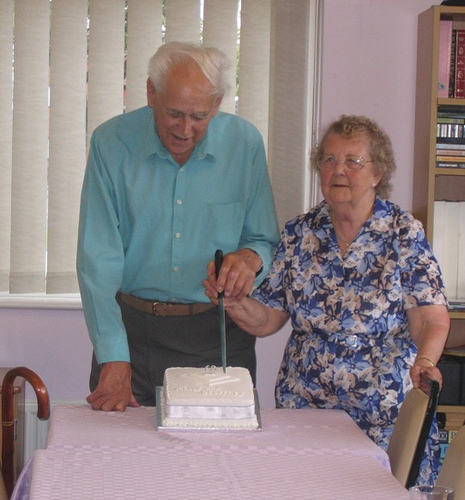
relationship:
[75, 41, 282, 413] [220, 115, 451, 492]
person with woman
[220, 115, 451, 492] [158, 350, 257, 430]
woman cutting cake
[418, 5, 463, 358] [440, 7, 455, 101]
bookcase has books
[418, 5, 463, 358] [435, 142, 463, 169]
bookcase has cassette tapes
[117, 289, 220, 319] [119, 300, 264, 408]
belt on pants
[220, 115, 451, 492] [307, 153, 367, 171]
woman wearing eyeglasses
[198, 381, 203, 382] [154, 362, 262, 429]
frosting on cake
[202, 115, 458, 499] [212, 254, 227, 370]
woman holding knife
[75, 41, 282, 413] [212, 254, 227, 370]
person holding knife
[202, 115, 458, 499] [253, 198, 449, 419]
woman wearing dress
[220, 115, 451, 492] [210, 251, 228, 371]
woman holding knife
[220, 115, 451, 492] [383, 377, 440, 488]
woman holding chair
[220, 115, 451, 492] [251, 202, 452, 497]
woman wearing dress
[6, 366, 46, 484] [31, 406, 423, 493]
cane on table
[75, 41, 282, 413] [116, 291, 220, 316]
person wearing belt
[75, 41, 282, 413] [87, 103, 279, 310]
person wearing shirt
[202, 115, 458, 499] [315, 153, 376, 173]
woman wearing eyeglasses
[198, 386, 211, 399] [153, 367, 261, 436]
frosting on cake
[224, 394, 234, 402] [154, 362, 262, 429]
icing on cake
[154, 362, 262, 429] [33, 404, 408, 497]
cake on table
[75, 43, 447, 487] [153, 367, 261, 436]
couple cutting cake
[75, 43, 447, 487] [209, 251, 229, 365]
couple holding knife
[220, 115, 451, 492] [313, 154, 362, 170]
woman wearing eyeglasses